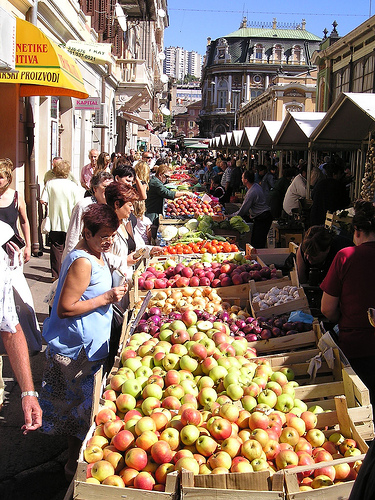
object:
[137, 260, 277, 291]
red apples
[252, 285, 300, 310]
white onions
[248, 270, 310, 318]
box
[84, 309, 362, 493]
apple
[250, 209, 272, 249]
pants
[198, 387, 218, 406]
apple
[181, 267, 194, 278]
apple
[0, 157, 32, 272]
woman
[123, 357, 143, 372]
green apple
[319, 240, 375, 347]
shirt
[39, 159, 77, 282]
lady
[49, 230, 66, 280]
pants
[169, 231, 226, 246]
lettuce heads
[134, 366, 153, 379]
apple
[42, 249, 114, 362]
blue shirt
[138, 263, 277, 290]
apples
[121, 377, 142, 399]
apple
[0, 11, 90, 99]
yellow awning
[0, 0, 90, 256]
building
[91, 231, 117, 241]
glasses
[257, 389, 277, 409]
apple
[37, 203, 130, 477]
man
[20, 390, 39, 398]
wrist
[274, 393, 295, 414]
apple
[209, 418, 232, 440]
apple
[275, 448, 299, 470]
apple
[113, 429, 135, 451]
apple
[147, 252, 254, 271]
aples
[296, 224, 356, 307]
woman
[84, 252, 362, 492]
fruit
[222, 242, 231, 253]
tomatoes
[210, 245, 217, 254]
tomatoes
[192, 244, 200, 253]
tomatoes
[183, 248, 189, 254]
tomatoes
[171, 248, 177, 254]
tomatoes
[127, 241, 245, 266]
box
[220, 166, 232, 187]
striped shirt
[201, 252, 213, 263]
apple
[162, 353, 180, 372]
apple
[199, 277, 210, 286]
apple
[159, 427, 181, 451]
apple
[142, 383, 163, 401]
apple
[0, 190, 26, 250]
top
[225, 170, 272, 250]
man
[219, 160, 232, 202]
man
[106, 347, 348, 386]
crate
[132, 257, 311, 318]
crate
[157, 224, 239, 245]
crate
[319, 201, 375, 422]
person